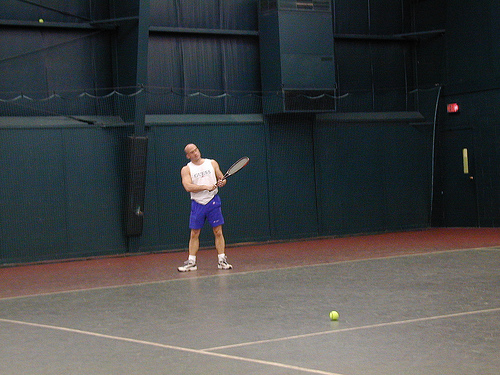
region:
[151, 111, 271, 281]
The man is inspecting the racket.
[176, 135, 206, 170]
The man is bald.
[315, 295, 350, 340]
A tennis ball is on the ground.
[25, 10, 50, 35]
A tennis ball is stuck on the ledge.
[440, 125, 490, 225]
A door.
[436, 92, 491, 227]
An exit sign is above the door.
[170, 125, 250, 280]
The man is holding the racket with both hands.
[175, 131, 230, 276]
The man is wearing a shirt with the sleeves cut off.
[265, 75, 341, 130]
A vent.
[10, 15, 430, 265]
The wall is dark green.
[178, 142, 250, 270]
a bald headed man playing tennis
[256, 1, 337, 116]
a green ventilation system mounted on the wall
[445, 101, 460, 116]
an exit sign above the door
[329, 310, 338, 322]
a fluorescent yellow tennis ball on the court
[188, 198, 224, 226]
the man is wearing purple tennis shorts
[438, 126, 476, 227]
a door on the side of the court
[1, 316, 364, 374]
the out of bounds lines are white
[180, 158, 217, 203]
the man is wearing a cut off t-shirt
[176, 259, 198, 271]
white and black tennis shoes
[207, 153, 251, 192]
a black and red tennis raquet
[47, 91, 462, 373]
man in blue shorts playing tennis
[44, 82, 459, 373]
male in blue shorts playing tennis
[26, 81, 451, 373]
man waiting to play tennis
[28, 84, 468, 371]
man holding tennis racket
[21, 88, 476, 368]
man standing on tennis court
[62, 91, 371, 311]
person in blue shorts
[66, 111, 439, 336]
athlete holding tennis racket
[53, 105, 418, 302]
athlete on tennis court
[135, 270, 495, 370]
green tennis ball on court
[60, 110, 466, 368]
athlete in white shirt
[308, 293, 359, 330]
a tennis ball laying on ground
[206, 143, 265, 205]
a black tennis racquet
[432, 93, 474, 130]
a red exit sign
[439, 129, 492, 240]
a black door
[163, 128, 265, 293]
a man playing tennis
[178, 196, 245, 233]
man in purple shorts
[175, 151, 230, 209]
man in white shirt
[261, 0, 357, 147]
black air condition vent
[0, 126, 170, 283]
foam padding on walls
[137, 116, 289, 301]
bald man in white tennis shoes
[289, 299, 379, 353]
the tennis ball is yellow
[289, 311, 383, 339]
the tennis ball is on the tennis court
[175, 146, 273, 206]
man is looking at his tennis racket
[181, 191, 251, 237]
man is wearing blue shorts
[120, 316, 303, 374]
white lines on the tennis court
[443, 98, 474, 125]
exit sign is red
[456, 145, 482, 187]
window in the door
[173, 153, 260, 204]
man's arms are muscular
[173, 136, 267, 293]
man standing on tennis court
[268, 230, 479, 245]
red ground around the tennis court